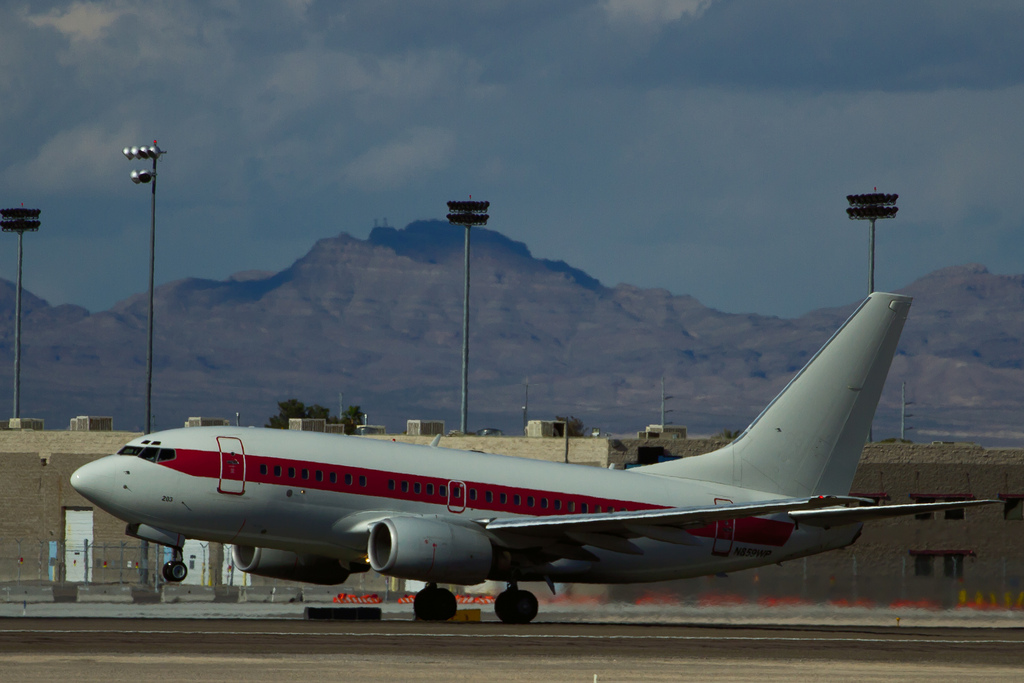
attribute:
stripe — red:
[70, 292, 1003, 616]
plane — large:
[51, 255, 965, 666]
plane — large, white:
[67, 297, 983, 669]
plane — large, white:
[63, 286, 992, 624]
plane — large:
[15, 325, 906, 615]